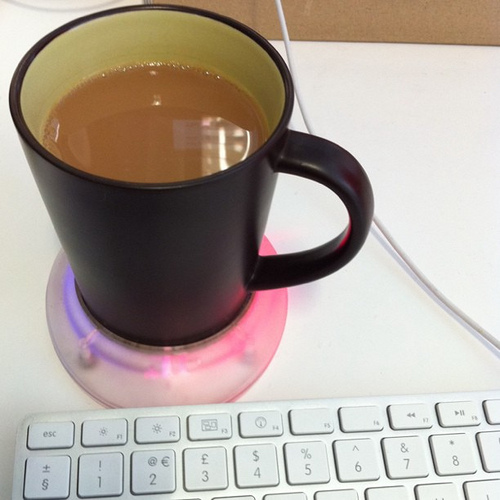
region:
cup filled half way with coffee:
[12, 13, 307, 188]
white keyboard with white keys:
[16, 413, 480, 496]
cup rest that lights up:
[20, 241, 357, 412]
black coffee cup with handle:
[20, 14, 379, 323]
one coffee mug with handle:
[13, 4, 375, 291]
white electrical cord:
[269, 6, 448, 316]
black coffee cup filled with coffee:
[15, 13, 389, 270]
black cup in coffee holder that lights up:
[13, 11, 334, 342]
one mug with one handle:
[16, 18, 393, 342]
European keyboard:
[17, 386, 486, 489]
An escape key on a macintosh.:
[27, 422, 75, 449]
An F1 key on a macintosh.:
[82, 418, 128, 446]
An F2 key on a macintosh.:
[133, 415, 178, 442]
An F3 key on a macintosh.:
[187, 413, 233, 442]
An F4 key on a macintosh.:
[237, 410, 282, 437]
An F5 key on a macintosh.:
[287, 408, 334, 435]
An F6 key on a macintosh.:
[337, 405, 384, 432]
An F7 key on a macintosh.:
[387, 403, 433, 430]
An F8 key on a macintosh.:
[436, 400, 483, 427]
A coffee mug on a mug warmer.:
[7, 3, 374, 408]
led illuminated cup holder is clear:
[27, 193, 339, 445]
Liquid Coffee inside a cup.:
[54, 91, 264, 146]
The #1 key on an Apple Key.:
[75, 453, 130, 499]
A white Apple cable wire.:
[396, 240, 499, 355]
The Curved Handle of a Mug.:
[282, 115, 377, 309]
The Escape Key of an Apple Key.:
[24, 420, 76, 452]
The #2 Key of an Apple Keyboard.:
[130, 450, 176, 495]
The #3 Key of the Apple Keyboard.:
[180, 449, 230, 487]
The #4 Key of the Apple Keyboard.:
[232, 445, 284, 487]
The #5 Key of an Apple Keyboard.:
[275, 445, 332, 485]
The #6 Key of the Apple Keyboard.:
[331, 438, 381, 482]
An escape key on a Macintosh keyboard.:
[27, 421, 75, 449]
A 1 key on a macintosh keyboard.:
[76, 452, 124, 499]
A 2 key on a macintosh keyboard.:
[129, 448, 176, 494]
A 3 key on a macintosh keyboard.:
[182, 445, 228, 492]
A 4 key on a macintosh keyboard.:
[232, 443, 280, 488]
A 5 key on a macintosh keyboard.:
[282, 440, 329, 485]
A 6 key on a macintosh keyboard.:
[333, 437, 380, 482]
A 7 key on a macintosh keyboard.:
[382, 434, 429, 479]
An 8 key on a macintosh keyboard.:
[429, 432, 476, 475]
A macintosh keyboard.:
[12, 390, 499, 498]